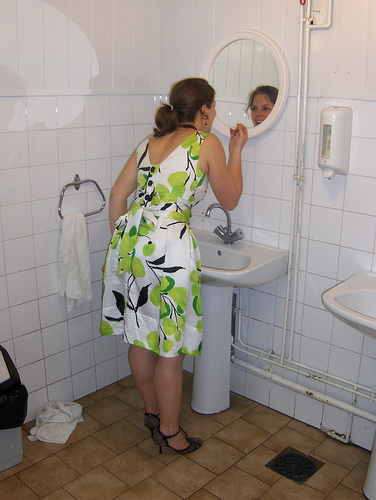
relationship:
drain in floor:
[262, 435, 334, 490] [35, 381, 368, 498]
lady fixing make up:
[85, 66, 260, 463] [137, 74, 251, 190]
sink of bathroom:
[189, 199, 291, 300] [6, 4, 374, 497]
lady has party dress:
[85, 66, 260, 463] [90, 125, 214, 358]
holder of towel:
[48, 167, 111, 219] [52, 202, 97, 314]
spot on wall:
[1, 4, 114, 143] [3, 6, 120, 385]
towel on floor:
[24, 392, 98, 454] [35, 381, 368, 498]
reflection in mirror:
[238, 78, 279, 126] [198, 27, 304, 145]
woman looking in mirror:
[85, 66, 260, 463] [198, 27, 304, 145]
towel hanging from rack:
[52, 202, 97, 314] [48, 167, 111, 219]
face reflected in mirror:
[238, 78, 279, 126] [198, 27, 304, 145]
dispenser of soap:
[311, 103, 355, 184] [316, 134, 341, 182]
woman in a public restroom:
[85, 66, 260, 463] [6, 4, 374, 497]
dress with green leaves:
[90, 125, 214, 358] [151, 173, 190, 202]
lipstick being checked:
[162, 72, 265, 153] [151, 30, 301, 151]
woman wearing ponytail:
[137, 74, 251, 190] [137, 68, 206, 140]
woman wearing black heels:
[85, 66, 260, 463] [137, 408, 210, 463]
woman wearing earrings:
[85, 66, 260, 463] [198, 114, 215, 129]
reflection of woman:
[238, 78, 279, 126] [85, 66, 260, 463]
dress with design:
[90, 125, 214, 358] [151, 173, 190, 202]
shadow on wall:
[283, 198, 374, 279] [233, 12, 373, 431]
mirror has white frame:
[198, 27, 304, 145] [203, 32, 287, 139]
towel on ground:
[24, 392, 98, 454] [44, 443, 145, 497]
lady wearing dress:
[99, 76, 248, 456] [98, 127, 203, 359]